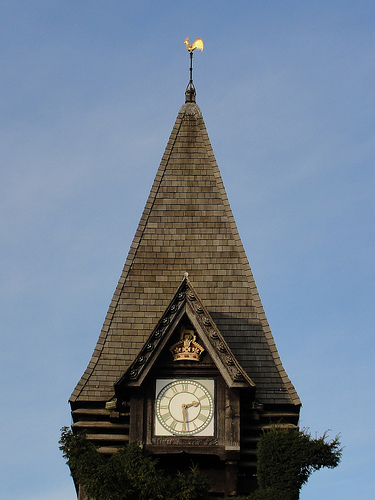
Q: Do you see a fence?
A: No, there are no fences.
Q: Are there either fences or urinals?
A: No, there are no fences or urinals.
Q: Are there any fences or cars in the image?
A: No, there are no cars or fences.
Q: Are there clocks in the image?
A: Yes, there is a clock.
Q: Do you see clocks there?
A: Yes, there is a clock.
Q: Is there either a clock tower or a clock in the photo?
A: Yes, there is a clock.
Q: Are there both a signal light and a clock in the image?
A: No, there is a clock but no traffic lights.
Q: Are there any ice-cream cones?
A: No, there are no ice-cream cones.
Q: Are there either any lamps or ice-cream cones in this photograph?
A: No, there are no ice-cream cones or lamps.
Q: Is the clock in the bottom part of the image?
A: Yes, the clock is in the bottom of the image.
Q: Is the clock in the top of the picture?
A: No, the clock is in the bottom of the image.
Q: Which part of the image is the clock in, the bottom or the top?
A: The clock is in the bottom of the image.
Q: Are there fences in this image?
A: No, there are no fences.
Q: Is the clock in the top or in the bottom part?
A: The clock is in the bottom of the image.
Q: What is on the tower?
A: The clock is on the tower.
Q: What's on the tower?
A: The clock is on the tower.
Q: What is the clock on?
A: The clock is on the tower.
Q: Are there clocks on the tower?
A: Yes, there is a clock on the tower.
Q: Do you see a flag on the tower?
A: No, there is a clock on the tower.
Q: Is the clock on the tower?
A: Yes, the clock is on the tower.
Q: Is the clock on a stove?
A: No, the clock is on the tower.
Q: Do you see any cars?
A: No, there are no cars.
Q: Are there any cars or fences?
A: No, there are no fences or cars.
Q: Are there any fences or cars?
A: No, there are no cars or fences.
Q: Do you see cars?
A: No, there are no cars.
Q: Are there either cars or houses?
A: No, there are no cars or houses.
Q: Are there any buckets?
A: No, there are no buckets.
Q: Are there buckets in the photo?
A: No, there are no buckets.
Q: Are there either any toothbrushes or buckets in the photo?
A: No, there are no buckets or toothbrushes.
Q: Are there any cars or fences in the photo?
A: No, there are no fences or cars.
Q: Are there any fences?
A: No, there are no fences.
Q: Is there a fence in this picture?
A: No, there are no fences.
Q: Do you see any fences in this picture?
A: No, there are no fences.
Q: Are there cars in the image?
A: No, there are no cars.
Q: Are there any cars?
A: No, there are no cars.